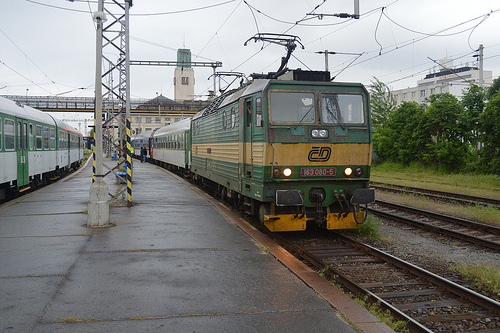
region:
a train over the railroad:
[141, 65, 391, 237]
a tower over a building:
[162, 39, 202, 111]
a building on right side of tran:
[378, 55, 495, 105]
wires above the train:
[10, 3, 497, 75]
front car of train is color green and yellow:
[185, 64, 384, 235]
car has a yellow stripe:
[187, 70, 379, 235]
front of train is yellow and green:
[256, 78, 380, 240]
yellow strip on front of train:
[258, 81, 379, 236]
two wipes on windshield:
[266, 81, 366, 128]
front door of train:
[233, 90, 262, 188]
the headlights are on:
[254, 132, 386, 216]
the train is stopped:
[62, 69, 387, 259]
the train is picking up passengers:
[64, 62, 391, 257]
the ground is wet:
[82, 172, 282, 328]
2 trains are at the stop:
[0, 97, 376, 277]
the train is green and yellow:
[228, 61, 398, 248]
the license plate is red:
[292, 162, 346, 184]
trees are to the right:
[357, 60, 487, 234]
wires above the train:
[176, 9, 436, 81]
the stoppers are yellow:
[252, 205, 376, 235]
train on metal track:
[200, 65, 397, 228]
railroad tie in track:
[381, 283, 428, 301]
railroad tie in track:
[394, 298, 449, 310]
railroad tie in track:
[424, 310, 472, 323]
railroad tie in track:
[345, 260, 396, 276]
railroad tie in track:
[320, 255, 367, 262]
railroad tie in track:
[456, 223, 471, 232]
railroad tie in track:
[479, 228, 491, 239]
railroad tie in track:
[389, 204, 402, 212]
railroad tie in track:
[382, 205, 391, 212]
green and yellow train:
[157, 106, 327, 200]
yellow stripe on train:
[196, 131, 363, 183]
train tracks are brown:
[301, 200, 448, 331]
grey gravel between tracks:
[370, 217, 495, 292]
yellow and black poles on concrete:
[94, 105, 152, 225]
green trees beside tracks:
[365, 92, 495, 182]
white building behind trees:
[375, 62, 488, 124]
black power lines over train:
[104, 0, 458, 75]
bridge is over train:
[37, 84, 211, 126]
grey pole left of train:
[73, 7, 174, 238]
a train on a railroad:
[145, 65, 386, 242]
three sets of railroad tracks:
[361, 178, 499, 329]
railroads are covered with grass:
[363, 175, 499, 325]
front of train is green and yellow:
[260, 77, 379, 232]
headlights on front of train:
[276, 161, 360, 183]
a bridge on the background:
[10, 82, 204, 122]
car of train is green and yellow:
[186, 66, 390, 236]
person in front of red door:
[138, 130, 159, 165]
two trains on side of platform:
[0, 58, 395, 246]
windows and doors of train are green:
[0, 108, 90, 193]